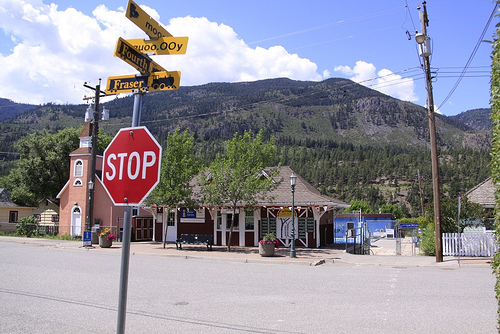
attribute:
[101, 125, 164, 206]
sign — stop sign, red, white, octagon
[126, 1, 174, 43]
sign — yellow, black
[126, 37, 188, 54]
sign — yellow, black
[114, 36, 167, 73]
sign — yellow, black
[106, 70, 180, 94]
sign — yellow, black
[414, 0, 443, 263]
utility pole — electrical, wooden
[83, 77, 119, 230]
utility pole — electrical, wooden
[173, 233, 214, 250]
bench — green, dark, empty, gray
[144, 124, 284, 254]
trees — green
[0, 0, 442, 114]
clouds — white, puffy, fluffy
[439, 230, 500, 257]
fence — white, wooden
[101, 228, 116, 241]
flowers — multi colored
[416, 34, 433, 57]
transformer — electrical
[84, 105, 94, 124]
transformer — electrical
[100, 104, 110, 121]
transformer — electrical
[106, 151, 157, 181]
lettering — white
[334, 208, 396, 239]
building — blue, small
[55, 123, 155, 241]
church — light red, little, red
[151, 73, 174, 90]
train — black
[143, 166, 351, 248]
building — red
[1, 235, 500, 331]
street — fraser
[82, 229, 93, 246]
sign — blue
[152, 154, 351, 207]
roof — gray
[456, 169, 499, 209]
roof — gray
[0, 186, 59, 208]
roof — gray